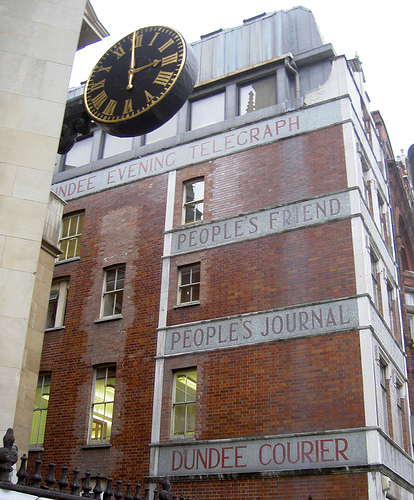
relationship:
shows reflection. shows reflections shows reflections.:
[182, 181, 201, 223] [236, 85, 259, 114]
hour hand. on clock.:
[133, 53, 160, 81] [74, 22, 209, 143]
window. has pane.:
[176, 168, 210, 230] [229, 106, 303, 121]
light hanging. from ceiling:
[69, 111, 97, 143] [67, 85, 105, 126]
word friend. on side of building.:
[268, 194, 348, 237] [371, 161, 410, 323]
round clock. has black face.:
[74, 22, 209, 143] [96, 56, 133, 97]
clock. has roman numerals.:
[74, 22, 209, 143] [154, 39, 186, 88]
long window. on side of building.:
[366, 247, 393, 333] [371, 161, 410, 323]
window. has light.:
[176, 168, 210, 230] [245, 85, 263, 114]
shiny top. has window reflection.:
[242, 61, 315, 122] [233, 82, 283, 120]